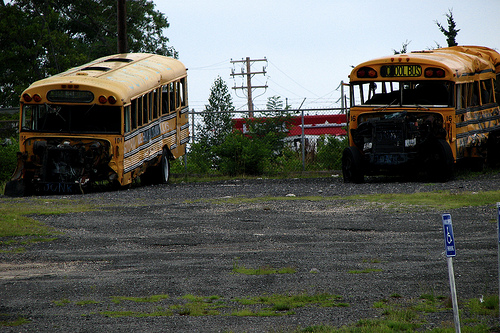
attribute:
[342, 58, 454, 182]
bus — broken, parked, destroyed, yellow, old, ruined, ruinied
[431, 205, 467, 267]
sign — blue